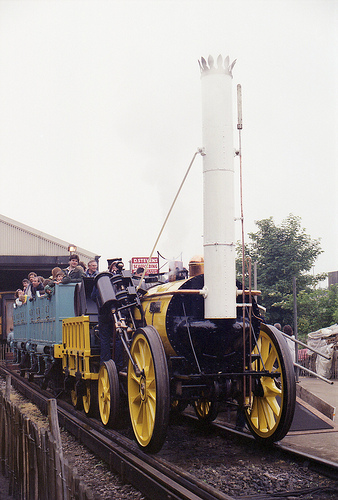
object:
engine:
[93, 165, 264, 364]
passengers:
[56, 268, 65, 282]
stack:
[193, 51, 245, 322]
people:
[85, 256, 100, 274]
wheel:
[125, 321, 172, 456]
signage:
[131, 256, 162, 277]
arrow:
[131, 252, 171, 269]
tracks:
[1, 368, 335, 494]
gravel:
[37, 401, 336, 496]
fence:
[1, 375, 72, 496]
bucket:
[12, 277, 81, 345]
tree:
[239, 210, 318, 307]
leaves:
[273, 250, 281, 260]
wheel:
[97, 359, 120, 427]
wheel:
[192, 399, 226, 422]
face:
[91, 262, 98, 269]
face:
[65, 256, 80, 269]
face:
[33, 279, 38, 286]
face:
[23, 283, 27, 287]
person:
[21, 278, 29, 289]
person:
[65, 255, 83, 269]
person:
[31, 273, 41, 287]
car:
[3, 52, 305, 467]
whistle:
[163, 257, 184, 278]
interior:
[128, 335, 156, 438]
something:
[147, 258, 150, 265]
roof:
[1, 208, 100, 267]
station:
[1, 206, 100, 349]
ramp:
[298, 376, 337, 429]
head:
[87, 258, 98, 271]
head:
[67, 254, 80, 267]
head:
[29, 275, 42, 287]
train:
[8, 42, 304, 452]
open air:
[5, 0, 330, 311]